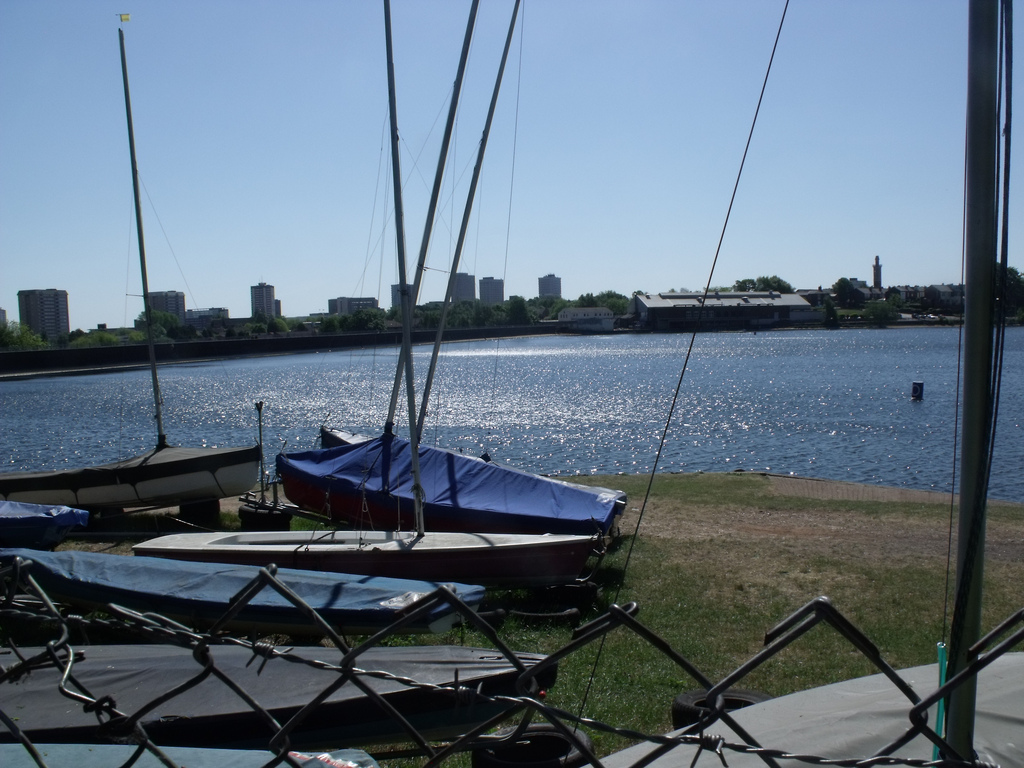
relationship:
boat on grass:
[280, 424, 631, 583] [438, 467, 1021, 744]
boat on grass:
[5, 435, 268, 509] [438, 467, 1021, 744]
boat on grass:
[131, 519, 612, 578] [438, 467, 1021, 744]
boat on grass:
[18, 549, 489, 639] [492, 467, 1020, 765]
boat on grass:
[5, 633, 560, 754] [492, 467, 1020, 765]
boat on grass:
[0, 732, 390, 767] [492, 467, 1020, 765]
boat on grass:
[595, 644, 1022, 766] [492, 467, 1020, 765]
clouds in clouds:
[177, 76, 305, 219] [0, 0, 1024, 332]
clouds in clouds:
[0, 0, 1024, 332] [0, 0, 1024, 332]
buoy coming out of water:
[911, 380, 925, 400] [0, 323, 1024, 479]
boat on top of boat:
[274, 432, 627, 557] [275, 421, 623, 540]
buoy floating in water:
[909, 376, 929, 403] [0, 323, 1022, 502]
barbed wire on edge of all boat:
[0, 557, 1024, 768] [588, 650, 1024, 768]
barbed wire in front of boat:
[0, 557, 1024, 768] [588, 650, 1024, 768]